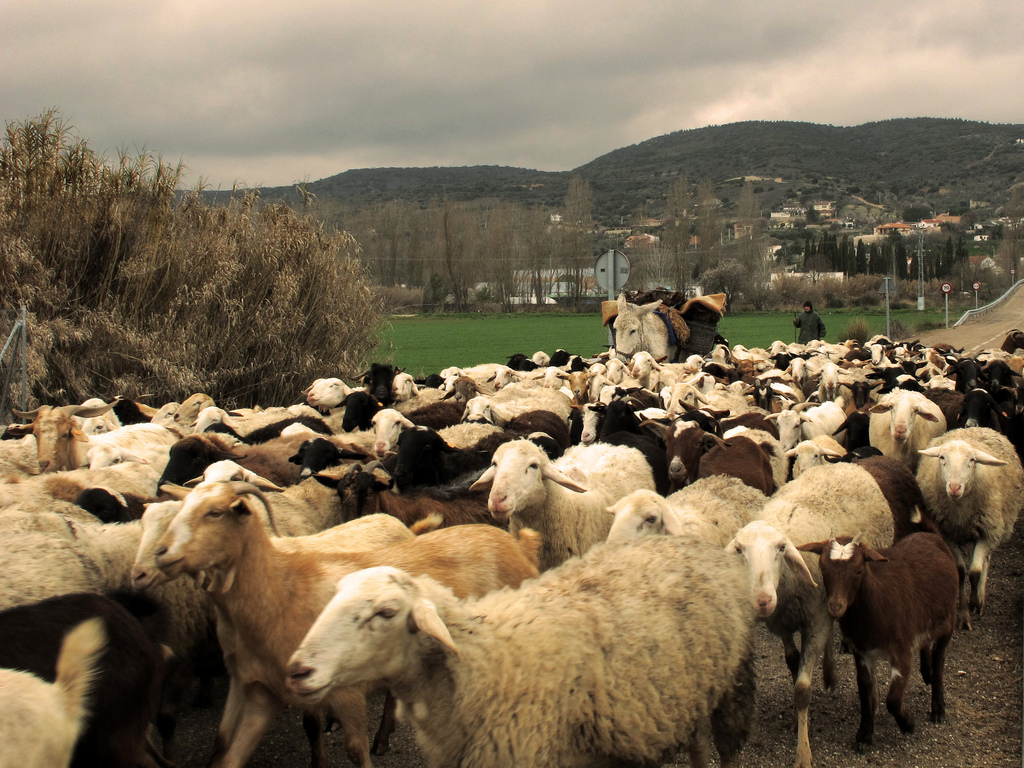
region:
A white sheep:
[279, 536, 745, 764]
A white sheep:
[912, 421, 1015, 612]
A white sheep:
[599, 471, 761, 533]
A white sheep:
[727, 461, 898, 765]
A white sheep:
[460, 389, 575, 427]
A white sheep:
[368, 407, 502, 461]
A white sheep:
[304, 373, 363, 412]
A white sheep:
[808, 358, 854, 398]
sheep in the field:
[162, 499, 467, 639]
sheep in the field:
[479, 455, 631, 520]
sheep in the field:
[197, 416, 341, 478]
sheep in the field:
[909, 421, 990, 543]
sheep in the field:
[792, 329, 897, 377]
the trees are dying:
[40, 168, 414, 419]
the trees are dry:
[58, 192, 376, 390]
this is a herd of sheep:
[64, 379, 766, 566]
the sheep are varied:
[315, 320, 996, 758]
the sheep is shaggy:
[342, 575, 842, 756]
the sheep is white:
[327, 569, 675, 683]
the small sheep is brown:
[810, 525, 976, 677]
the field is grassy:
[386, 291, 693, 384]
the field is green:
[356, 253, 595, 375]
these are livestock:
[152, 402, 804, 703]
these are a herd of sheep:
[298, 423, 751, 762]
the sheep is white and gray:
[339, 563, 584, 718]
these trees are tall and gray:
[87, 165, 306, 363]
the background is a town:
[646, 142, 1011, 408]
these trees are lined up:
[339, 183, 713, 364]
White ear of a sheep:
[396, 583, 474, 672]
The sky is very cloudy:
[2, 2, 1018, 196]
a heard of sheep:
[0, 291, 1023, 741]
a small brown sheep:
[767, 505, 982, 731]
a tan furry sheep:
[300, 522, 759, 758]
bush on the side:
[1, 107, 395, 390]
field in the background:
[347, 269, 619, 362]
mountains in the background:
[287, 104, 987, 209]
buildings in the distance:
[708, 168, 958, 268]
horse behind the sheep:
[597, 281, 735, 355]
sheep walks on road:
[293, 532, 755, 767]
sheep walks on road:
[725, 463, 893, 767]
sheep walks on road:
[601, 469, 772, 556]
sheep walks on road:
[465, 439, 653, 573]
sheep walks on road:
[940, 357, 979, 393]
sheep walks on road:
[977, 360, 1019, 393]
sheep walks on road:
[440, 373, 486, 405]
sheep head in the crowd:
[258, 551, 456, 703]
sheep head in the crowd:
[152, 469, 269, 586]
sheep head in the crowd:
[463, 438, 581, 537]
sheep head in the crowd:
[718, 514, 810, 632]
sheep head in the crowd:
[899, 434, 1004, 517]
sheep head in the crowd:
[621, 346, 672, 392]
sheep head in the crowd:
[459, 393, 513, 447]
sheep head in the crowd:
[356, 400, 415, 455]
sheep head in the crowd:
[302, 369, 357, 417]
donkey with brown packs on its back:
[589, 284, 735, 360]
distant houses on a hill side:
[583, 170, 919, 298]